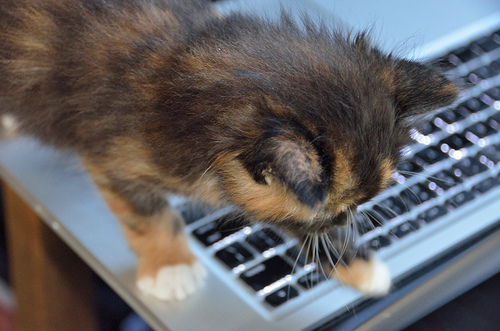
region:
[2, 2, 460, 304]
A kitty on a keyboard.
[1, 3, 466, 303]
A kitty with white paws.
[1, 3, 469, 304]
A black and brown kitty.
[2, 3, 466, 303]
A kitten on a laptop.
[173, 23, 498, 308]
A keyboard with keys.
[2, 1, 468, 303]
A brown kitten on a keyboard.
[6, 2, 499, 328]
A laptop with keyboard.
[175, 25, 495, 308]
Keys on a keyboard.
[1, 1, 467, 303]
A kitten with white paws.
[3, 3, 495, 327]
A silver laptops keyboard.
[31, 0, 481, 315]
a kitten on a key board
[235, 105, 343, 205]
the ear of a cat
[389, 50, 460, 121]
the ear of a cat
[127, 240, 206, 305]
the paw of a kitten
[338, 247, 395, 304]
the paw of a kitten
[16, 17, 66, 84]
the fur of a cat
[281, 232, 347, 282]
the whiskers of a cat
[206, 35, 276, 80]
the fur of a kitten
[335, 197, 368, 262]
the eyelashes of a cat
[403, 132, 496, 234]
the keys on a keyboard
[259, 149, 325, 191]
Cat has black ear.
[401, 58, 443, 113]
Cat has black and brown ear.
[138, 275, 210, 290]
Tip of cat's paw is white.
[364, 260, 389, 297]
Tip of cat's paw is white.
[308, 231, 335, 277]
Cat has white whiskers.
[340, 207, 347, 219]
Cat has black nose.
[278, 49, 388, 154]
Cat has black fur on top of head.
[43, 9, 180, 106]
Cat has black and brown back.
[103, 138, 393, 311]
Cat is standing on keyboard.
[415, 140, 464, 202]
Buttons on keyboard are black.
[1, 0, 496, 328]
a brown and black cat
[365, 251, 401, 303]
right paw of cat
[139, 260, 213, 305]
left paw of cat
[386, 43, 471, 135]
right ear of cat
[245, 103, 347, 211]
left ear of cat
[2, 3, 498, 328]
cat is on a laptop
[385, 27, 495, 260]
laptop has silver keyboard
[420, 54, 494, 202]
buttons of keyboard are black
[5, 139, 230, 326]
laptop is on a desk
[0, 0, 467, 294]
cat has black stripes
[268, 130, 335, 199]
Dark brown and black fur on animal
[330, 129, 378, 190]
Dark brown and black fur on animal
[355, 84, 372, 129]
Dark brown and black fur on animal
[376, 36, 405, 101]
Dark brown and black fur on animal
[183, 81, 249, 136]
Dark brown and black fur on animal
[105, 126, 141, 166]
Dark brown and black fur on animal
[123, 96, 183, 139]
Dark brown and black fur on animal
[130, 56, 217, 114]
Dark brown and black fur on animal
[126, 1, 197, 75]
Dark brown and black fur on animal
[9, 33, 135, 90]
Dark brown and black fur on animal